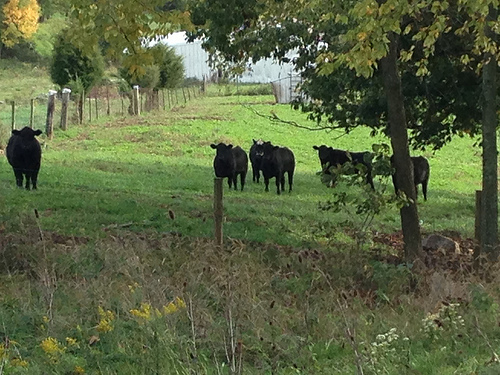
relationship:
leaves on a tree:
[73, 232, 274, 326] [0, 2, 42, 52]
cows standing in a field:
[4, 124, 436, 202] [6, 69, 498, 373]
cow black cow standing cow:
[4, 125, 42, 191] [4, 125, 42, 191]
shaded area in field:
[19, 174, 461, 320] [28, 44, 428, 320]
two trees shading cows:
[178, 8, 487, 283] [199, 125, 316, 196]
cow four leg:
[209, 142, 248, 192] [227, 176, 233, 190]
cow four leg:
[209, 142, 248, 192] [238, 175, 246, 190]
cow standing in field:
[15, 114, 95, 196] [81, 109, 476, 260]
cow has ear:
[206, 133, 251, 192] [205, 130, 220, 150]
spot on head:
[256, 140, 262, 145] [255, 138, 266, 157]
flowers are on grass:
[355, 300, 472, 367] [2, 57, 499, 372]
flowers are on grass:
[129, 295, 186, 319] [2, 57, 499, 372]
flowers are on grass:
[92, 305, 115, 331] [2, 57, 499, 372]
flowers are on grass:
[38, 335, 81, 359] [2, 57, 499, 372]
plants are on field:
[195, 232, 252, 370] [0, 56, 500, 375]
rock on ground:
[422, 228, 460, 260] [0, 63, 499, 374]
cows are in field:
[10, 121, 480, 217] [6, 69, 498, 373]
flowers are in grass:
[365, 299, 468, 359] [41, 142, 202, 221]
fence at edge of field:
[4, 76, 294, 147] [6, 69, 498, 373]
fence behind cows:
[239, 71, 320, 111] [197, 131, 444, 205]